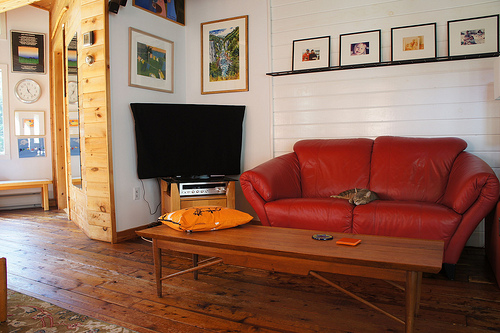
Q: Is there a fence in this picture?
A: No, there are no fences.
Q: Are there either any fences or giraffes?
A: No, there are no fences or giraffes.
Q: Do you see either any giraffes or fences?
A: No, there are no fences or giraffes.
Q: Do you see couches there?
A: Yes, there is a couch.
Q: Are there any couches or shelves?
A: Yes, there is a couch.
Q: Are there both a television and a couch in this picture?
A: Yes, there are both a couch and a television.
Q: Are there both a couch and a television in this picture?
A: Yes, there are both a couch and a television.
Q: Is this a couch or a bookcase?
A: This is a couch.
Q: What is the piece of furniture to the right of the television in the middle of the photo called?
A: The piece of furniture is a couch.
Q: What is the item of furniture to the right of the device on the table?
A: The piece of furniture is a couch.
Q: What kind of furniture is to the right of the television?
A: The piece of furniture is a couch.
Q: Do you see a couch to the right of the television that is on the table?
A: Yes, there is a couch to the right of the TV.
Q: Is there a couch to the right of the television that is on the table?
A: Yes, there is a couch to the right of the TV.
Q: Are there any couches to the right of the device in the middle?
A: Yes, there is a couch to the right of the TV.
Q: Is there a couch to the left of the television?
A: No, the couch is to the right of the television.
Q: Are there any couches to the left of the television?
A: No, the couch is to the right of the television.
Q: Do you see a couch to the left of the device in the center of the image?
A: No, the couch is to the right of the television.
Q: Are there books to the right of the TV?
A: No, there is a couch to the right of the TV.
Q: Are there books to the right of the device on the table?
A: No, there is a couch to the right of the TV.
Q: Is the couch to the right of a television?
A: Yes, the couch is to the right of a television.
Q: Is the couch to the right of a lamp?
A: No, the couch is to the right of a television.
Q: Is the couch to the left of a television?
A: No, the couch is to the right of a television.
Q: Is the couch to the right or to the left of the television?
A: The couch is to the right of the television.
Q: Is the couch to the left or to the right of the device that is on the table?
A: The couch is to the right of the television.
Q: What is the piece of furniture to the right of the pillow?
A: The piece of furniture is a couch.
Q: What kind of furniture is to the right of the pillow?
A: The piece of furniture is a couch.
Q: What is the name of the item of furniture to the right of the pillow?
A: The piece of furniture is a couch.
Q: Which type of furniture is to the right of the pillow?
A: The piece of furniture is a couch.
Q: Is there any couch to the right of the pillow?
A: Yes, there is a couch to the right of the pillow.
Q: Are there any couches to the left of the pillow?
A: No, the couch is to the right of the pillow.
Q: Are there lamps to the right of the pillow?
A: No, there is a couch to the right of the pillow.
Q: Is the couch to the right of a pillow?
A: Yes, the couch is to the right of a pillow.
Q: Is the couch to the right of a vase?
A: No, the couch is to the right of a pillow.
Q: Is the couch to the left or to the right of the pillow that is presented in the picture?
A: The couch is to the right of the pillow.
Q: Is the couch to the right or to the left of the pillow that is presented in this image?
A: The couch is to the right of the pillow.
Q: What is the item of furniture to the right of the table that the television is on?
A: The piece of furniture is a couch.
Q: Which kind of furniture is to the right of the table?
A: The piece of furniture is a couch.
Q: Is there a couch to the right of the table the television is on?
A: Yes, there is a couch to the right of the table.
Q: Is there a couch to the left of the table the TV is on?
A: No, the couch is to the right of the table.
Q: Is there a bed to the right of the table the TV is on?
A: No, there is a couch to the right of the table.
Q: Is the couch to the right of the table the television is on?
A: Yes, the couch is to the right of the table.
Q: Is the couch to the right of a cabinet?
A: No, the couch is to the right of the table.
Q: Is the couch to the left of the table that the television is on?
A: No, the couch is to the right of the table.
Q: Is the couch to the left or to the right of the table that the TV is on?
A: The couch is to the right of the table.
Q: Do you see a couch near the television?
A: Yes, there is a couch near the television.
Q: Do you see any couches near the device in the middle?
A: Yes, there is a couch near the television.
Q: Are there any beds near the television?
A: No, there is a couch near the television.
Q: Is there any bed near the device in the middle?
A: No, there is a couch near the television.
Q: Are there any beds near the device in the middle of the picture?
A: No, there is a couch near the television.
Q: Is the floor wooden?
A: Yes, the floor is wooden.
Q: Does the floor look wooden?
A: Yes, the floor is wooden.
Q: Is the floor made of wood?
A: Yes, the floor is made of wood.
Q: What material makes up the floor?
A: The floor is made of wood.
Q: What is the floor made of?
A: The floor is made of wood.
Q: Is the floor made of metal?
A: No, the floor is made of wood.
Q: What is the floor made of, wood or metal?
A: The floor is made of wood.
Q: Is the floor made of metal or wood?
A: The floor is made of wood.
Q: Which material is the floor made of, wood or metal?
A: The floor is made of wood.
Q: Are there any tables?
A: Yes, there is a table.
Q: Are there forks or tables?
A: Yes, there is a table.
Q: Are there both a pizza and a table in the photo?
A: No, there is a table but no pizzas.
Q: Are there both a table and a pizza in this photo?
A: No, there is a table but no pizzas.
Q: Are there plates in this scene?
A: No, there are no plates.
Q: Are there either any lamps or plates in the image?
A: No, there are no plates or lamps.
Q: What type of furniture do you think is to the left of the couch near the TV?
A: The piece of furniture is a table.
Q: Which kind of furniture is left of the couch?
A: The piece of furniture is a table.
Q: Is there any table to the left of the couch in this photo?
A: Yes, there is a table to the left of the couch.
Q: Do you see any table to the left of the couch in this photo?
A: Yes, there is a table to the left of the couch.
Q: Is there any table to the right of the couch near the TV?
A: No, the table is to the left of the couch.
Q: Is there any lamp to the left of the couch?
A: No, there is a table to the left of the couch.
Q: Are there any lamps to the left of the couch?
A: No, there is a table to the left of the couch.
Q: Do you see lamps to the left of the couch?
A: No, there is a table to the left of the couch.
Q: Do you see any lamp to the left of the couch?
A: No, there is a table to the left of the couch.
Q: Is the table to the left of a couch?
A: Yes, the table is to the left of a couch.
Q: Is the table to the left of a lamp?
A: No, the table is to the left of a couch.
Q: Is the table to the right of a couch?
A: No, the table is to the left of a couch.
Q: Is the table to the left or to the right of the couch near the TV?
A: The table is to the left of the couch.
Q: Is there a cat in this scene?
A: Yes, there is a cat.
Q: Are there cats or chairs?
A: Yes, there is a cat.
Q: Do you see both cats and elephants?
A: No, there is a cat but no elephants.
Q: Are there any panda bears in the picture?
A: No, there are no panda bears.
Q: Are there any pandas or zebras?
A: No, there are no pandas or zebras.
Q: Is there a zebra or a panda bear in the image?
A: No, there are no pandas or zebras.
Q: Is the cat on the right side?
A: Yes, the cat is on the right of the image.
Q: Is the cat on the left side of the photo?
A: No, the cat is on the right of the image.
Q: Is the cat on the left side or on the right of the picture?
A: The cat is on the right of the image.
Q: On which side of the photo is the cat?
A: The cat is on the right of the image.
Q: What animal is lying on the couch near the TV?
A: The cat is lying on the couch.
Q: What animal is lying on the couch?
A: The cat is lying on the couch.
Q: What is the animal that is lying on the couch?
A: The animal is a cat.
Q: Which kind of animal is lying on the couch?
A: The animal is a cat.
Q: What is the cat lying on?
A: The cat is lying on the couch.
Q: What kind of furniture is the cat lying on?
A: The cat is lying on the couch.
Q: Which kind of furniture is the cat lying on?
A: The cat is lying on the couch.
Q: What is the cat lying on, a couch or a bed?
A: The cat is lying on a couch.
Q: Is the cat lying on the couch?
A: Yes, the cat is lying on the couch.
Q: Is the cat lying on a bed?
A: No, the cat is lying on the couch.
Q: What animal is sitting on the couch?
A: The cat is sitting on the couch.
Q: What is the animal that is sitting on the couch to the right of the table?
A: The animal is a cat.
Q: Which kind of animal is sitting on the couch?
A: The animal is a cat.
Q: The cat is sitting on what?
A: The cat is sitting on the couch.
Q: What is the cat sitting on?
A: The cat is sitting on the couch.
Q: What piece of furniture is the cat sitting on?
A: The cat is sitting on the couch.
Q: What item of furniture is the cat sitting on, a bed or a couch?
A: The cat is sitting on a couch.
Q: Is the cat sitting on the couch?
A: Yes, the cat is sitting on the couch.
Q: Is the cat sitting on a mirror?
A: No, the cat is sitting on the couch.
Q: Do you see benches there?
A: Yes, there is a bench.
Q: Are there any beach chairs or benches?
A: Yes, there is a bench.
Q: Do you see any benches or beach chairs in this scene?
A: Yes, there is a bench.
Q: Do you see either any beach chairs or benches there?
A: Yes, there is a bench.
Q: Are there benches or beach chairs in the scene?
A: Yes, there is a bench.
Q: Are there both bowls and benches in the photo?
A: No, there is a bench but no bowls.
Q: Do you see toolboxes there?
A: No, there are no toolboxes.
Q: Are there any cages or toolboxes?
A: No, there are no toolboxes or cages.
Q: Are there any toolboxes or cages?
A: No, there are no toolboxes or cages.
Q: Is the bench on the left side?
A: Yes, the bench is on the left of the image.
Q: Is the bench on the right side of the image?
A: No, the bench is on the left of the image.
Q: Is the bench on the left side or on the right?
A: The bench is on the left of the image.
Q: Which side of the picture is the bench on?
A: The bench is on the left of the image.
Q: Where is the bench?
A: The bench is on the floor.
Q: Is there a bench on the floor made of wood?
A: Yes, there is a bench on the floor.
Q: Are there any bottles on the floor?
A: No, there is a bench on the floor.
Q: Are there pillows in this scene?
A: Yes, there is a pillow.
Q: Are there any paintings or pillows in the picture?
A: Yes, there is a pillow.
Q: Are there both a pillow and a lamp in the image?
A: No, there is a pillow but no lamps.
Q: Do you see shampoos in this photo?
A: No, there are no shampoos.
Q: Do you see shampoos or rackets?
A: No, there are no shampoos or rackets.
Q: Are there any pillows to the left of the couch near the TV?
A: Yes, there is a pillow to the left of the couch.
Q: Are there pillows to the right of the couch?
A: No, the pillow is to the left of the couch.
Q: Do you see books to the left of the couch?
A: No, there is a pillow to the left of the couch.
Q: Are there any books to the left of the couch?
A: No, there is a pillow to the left of the couch.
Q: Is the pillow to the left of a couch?
A: Yes, the pillow is to the left of a couch.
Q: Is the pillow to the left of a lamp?
A: No, the pillow is to the left of a couch.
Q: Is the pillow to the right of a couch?
A: No, the pillow is to the left of a couch.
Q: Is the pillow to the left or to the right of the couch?
A: The pillow is to the left of the couch.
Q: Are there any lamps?
A: No, there are no lamps.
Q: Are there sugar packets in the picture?
A: No, there are no sugar packets.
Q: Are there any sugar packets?
A: No, there are no sugar packets.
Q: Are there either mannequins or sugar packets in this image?
A: No, there are no sugar packets or mannequins.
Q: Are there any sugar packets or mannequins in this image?
A: No, there are no sugar packets or mannequins.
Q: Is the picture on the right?
A: Yes, the picture is on the right of the image.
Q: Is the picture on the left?
A: No, the picture is on the right of the image.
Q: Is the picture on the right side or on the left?
A: The picture is on the right of the image.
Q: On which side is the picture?
A: The picture is on the right of the image.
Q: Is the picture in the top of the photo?
A: Yes, the picture is in the top of the image.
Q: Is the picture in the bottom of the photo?
A: No, the picture is in the top of the image.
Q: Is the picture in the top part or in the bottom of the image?
A: The picture is in the top of the image.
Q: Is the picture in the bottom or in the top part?
A: The picture is in the top of the image.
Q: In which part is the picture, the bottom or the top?
A: The picture is in the top of the image.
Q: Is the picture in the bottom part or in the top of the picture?
A: The picture is in the top of the image.